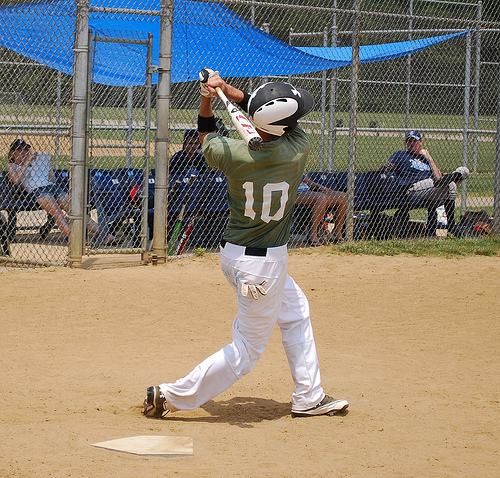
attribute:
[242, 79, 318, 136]
helmet — black, white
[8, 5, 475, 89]
cloth — blue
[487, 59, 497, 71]
leaf — green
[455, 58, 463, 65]
leaf — green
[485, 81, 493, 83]
leaf — green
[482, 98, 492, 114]
leaf — green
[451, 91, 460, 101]
leaf — green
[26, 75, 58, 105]
leaves — green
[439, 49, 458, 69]
leaves — green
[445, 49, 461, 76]
tree — green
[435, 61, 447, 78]
leaves — green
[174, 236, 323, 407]
pants — white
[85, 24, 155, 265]
door — metal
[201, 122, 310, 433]
uniform — green, white